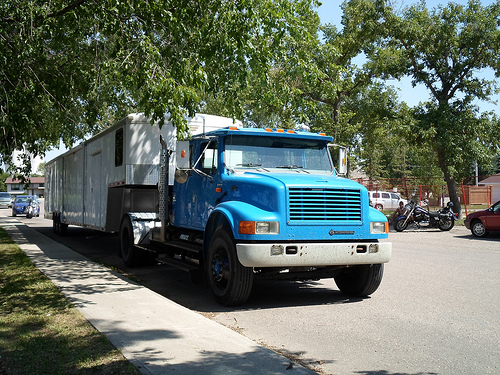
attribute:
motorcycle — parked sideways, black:
[388, 181, 460, 238]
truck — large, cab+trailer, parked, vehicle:
[37, 109, 403, 313]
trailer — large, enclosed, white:
[41, 107, 252, 268]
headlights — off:
[255, 216, 385, 239]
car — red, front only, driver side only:
[459, 200, 499, 240]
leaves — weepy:
[1, 0, 331, 176]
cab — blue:
[172, 119, 394, 313]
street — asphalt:
[15, 196, 499, 374]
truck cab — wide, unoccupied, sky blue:
[172, 122, 397, 312]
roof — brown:
[476, 169, 500, 185]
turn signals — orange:
[238, 221, 390, 235]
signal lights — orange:
[236, 218, 394, 236]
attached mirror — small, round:
[170, 167, 193, 186]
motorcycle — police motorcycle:
[20, 192, 45, 221]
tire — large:
[203, 223, 256, 310]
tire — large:
[329, 258, 387, 301]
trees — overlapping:
[277, 0, 500, 223]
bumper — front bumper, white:
[232, 239, 395, 275]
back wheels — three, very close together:
[51, 209, 70, 238]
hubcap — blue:
[207, 251, 228, 283]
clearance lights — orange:
[224, 125, 329, 137]